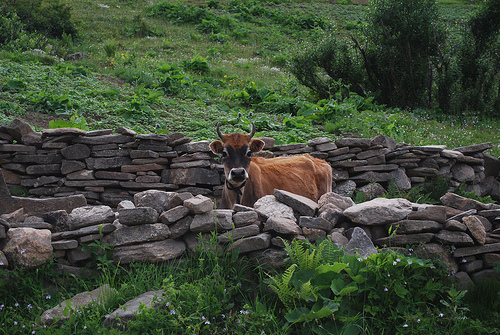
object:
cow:
[209, 122, 332, 207]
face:
[209, 133, 264, 183]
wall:
[0, 125, 221, 192]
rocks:
[61, 145, 90, 160]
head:
[206, 122, 265, 185]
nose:
[232, 169, 245, 180]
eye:
[247, 152, 253, 158]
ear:
[251, 139, 266, 153]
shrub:
[282, 240, 454, 328]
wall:
[1, 190, 500, 296]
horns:
[247, 122, 256, 136]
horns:
[215, 121, 225, 137]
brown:
[268, 162, 303, 179]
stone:
[387, 223, 440, 233]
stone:
[441, 192, 485, 212]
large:
[353, 1, 436, 106]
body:
[209, 121, 332, 209]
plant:
[92, 229, 114, 281]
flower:
[384, 287, 389, 292]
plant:
[366, 251, 445, 320]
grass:
[251, 11, 316, 43]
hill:
[0, 0, 500, 186]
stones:
[104, 290, 168, 325]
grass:
[2, 269, 199, 334]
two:
[216, 121, 256, 136]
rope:
[226, 179, 247, 204]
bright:
[262, 201, 278, 214]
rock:
[255, 195, 296, 223]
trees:
[290, 31, 367, 99]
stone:
[4, 227, 53, 269]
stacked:
[111, 193, 216, 265]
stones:
[115, 207, 159, 223]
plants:
[237, 77, 382, 123]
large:
[343, 197, 412, 227]